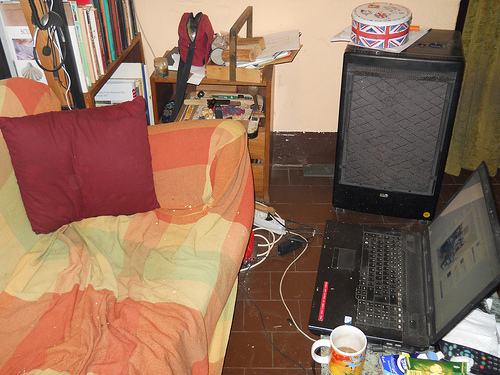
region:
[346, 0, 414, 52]
Round can with British flag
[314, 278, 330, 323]
Red label with white words on laptop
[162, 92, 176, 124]
Remote control on bookshelf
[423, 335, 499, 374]
Remote control on floor behind laptap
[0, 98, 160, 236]
Large square pillow on sofa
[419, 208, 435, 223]
Small yellow circular sticker on speaker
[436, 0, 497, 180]
Olive green curtain near speaker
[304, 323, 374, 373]
White ceramic mug with little coffee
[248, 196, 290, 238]
White power strip on floor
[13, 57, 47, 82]
Inverted shell taped on bookshelf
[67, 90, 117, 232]
Red pillow on couch.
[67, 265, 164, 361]
Couch is red, orange, and yellow.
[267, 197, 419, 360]
Black laptop on table.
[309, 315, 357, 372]
Multi colored coffee mug on table.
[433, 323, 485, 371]
Black remote control on table.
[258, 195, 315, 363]
Many cords plugged in to power strip on floor.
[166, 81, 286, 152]
Wood shelf near couch.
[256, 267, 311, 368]
Floor is made of brown tiles.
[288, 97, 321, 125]
Wall is painted cream color.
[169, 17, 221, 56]
Red bag on wood shelf.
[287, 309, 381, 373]
a coffee mug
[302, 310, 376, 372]
a coffee mug with coffee in it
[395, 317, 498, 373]
a black remote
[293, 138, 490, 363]
a black laptop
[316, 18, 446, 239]
a tall black speaker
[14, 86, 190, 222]
a red pillow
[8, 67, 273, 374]
a couch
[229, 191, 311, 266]
a white power strip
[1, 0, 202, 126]
a bookcase with books in it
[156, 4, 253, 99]
a red bag on a table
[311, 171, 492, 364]
the laptop is black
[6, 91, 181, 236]
the pillow is red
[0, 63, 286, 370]
the couch is orange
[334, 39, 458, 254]
the speaker is black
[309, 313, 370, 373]
coffee mug next to laptop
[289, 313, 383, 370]
coffee is in the mug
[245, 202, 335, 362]
white cord on floor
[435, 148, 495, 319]
the laptop is on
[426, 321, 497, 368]
remote control behind laptop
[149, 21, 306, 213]
cabinet made of wood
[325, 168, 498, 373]
A laptop sitting on the table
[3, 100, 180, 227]
Burgundy pillow on couch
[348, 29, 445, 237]
Heater in corner of room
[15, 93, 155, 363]
Cover on the couch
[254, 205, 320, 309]
Extension cord on floor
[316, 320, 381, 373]
Coffee in the mug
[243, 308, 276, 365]
Tile on the floor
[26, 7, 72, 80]
Headphones hanging up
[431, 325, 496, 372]
Remote control on table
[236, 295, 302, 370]
The floor is dirty